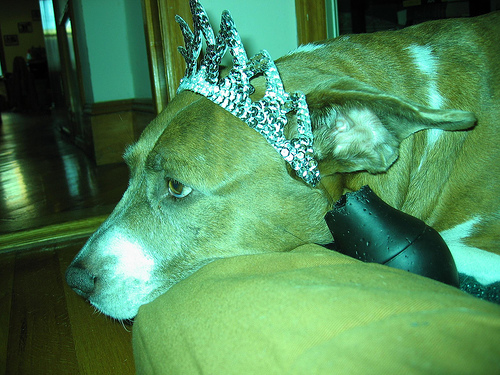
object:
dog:
[65, 8, 499, 321]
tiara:
[173, 1, 321, 186]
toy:
[326, 181, 460, 291]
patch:
[409, 42, 449, 175]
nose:
[65, 267, 94, 299]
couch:
[130, 241, 500, 373]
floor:
[2, 105, 70, 313]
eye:
[168, 178, 194, 199]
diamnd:
[248, 106, 259, 118]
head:
[65, 56, 333, 320]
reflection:
[2, 119, 28, 221]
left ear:
[309, 79, 477, 176]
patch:
[99, 226, 158, 319]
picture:
[3, 33, 18, 47]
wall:
[1, 2, 43, 74]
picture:
[17, 22, 34, 35]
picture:
[32, 8, 42, 21]